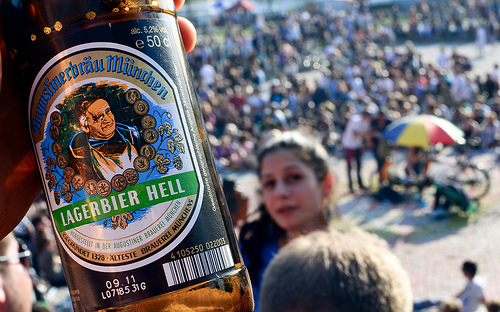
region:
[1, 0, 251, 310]
the bottle of beer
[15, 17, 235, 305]
the label on the beer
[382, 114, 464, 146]
the multi-colored umbrella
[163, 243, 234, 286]
the barcode on the label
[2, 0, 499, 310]
the people behind the bottle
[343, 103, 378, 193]
the person standing near the umbrella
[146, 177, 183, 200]
the word HELL on the label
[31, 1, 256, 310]
close up of beer bottle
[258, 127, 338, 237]
woman looking at camera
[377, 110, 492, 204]
multi colored umbrella on bike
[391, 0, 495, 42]
group standing to right of crowd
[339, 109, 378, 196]
man in red shorts standing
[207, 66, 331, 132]
crowd of people sitting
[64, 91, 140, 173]
cartoon character on bottle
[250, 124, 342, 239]
woman smiling at camera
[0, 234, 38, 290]
man wearing silver glasses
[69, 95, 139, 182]
print of a man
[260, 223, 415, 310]
short dry gray hair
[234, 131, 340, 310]
woman in blue shirt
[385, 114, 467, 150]
red yellow and blue umbrella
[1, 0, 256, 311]
hand holding a glass bottle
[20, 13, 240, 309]
black label on a glass bottle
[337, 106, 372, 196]
man wearing white shirt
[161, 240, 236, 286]
black and white barcode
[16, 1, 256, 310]
amber glass bottle with label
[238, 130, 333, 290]
pretty girl with black hair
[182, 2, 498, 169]
crowd of people behind beer bottle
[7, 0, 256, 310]
large brown beer bottle is empty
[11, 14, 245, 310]
label glued to beer bottle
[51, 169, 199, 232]
green stripe printed across label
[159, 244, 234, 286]
black and white UPC code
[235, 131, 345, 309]
woman has long brown hair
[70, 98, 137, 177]
man pictured on label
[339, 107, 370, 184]
person standing near umbrella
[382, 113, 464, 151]
umbrella is open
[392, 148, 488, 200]
bicycle behind umbrella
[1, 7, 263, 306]
a brown beer bottle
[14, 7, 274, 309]
blue label on bottle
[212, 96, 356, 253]
this is a woman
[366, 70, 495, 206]
umbrella in the background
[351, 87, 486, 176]
the umbrella is multicolored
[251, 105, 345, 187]
woman has dark hair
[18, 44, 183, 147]
blue writing on label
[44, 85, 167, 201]
male drawing on label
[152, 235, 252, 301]
barcode on the label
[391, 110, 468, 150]
the umbrella is colorful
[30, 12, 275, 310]
beer bottle is brown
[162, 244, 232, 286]
the bar code is white